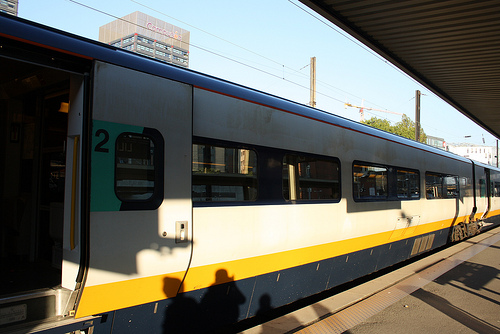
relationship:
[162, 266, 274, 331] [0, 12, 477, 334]
shadow on surface of train car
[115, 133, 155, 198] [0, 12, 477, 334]
window on train car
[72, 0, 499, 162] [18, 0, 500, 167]
wires against sky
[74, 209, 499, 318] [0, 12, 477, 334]
stripe painted on train car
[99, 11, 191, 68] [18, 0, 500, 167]
building visible in sky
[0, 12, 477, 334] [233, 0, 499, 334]
train car stopped at station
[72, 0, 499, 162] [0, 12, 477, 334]
wires behind train car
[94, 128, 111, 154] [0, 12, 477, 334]
number printed on train car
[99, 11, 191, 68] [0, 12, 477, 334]
building behind train car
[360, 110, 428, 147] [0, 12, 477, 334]
trees behind train car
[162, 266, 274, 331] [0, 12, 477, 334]
shadow visible on train car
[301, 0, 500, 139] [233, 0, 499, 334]
overhang over station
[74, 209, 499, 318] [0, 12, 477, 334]
stripe on outside of train car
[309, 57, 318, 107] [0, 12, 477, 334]
pole behind train car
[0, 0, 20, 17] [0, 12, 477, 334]
building behind train car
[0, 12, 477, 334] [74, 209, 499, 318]
train car has stripe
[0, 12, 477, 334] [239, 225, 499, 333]
train car next to platform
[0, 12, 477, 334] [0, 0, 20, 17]
train car in front of building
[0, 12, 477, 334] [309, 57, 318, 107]
train car in front of pole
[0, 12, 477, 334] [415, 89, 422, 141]
train car in front of pole